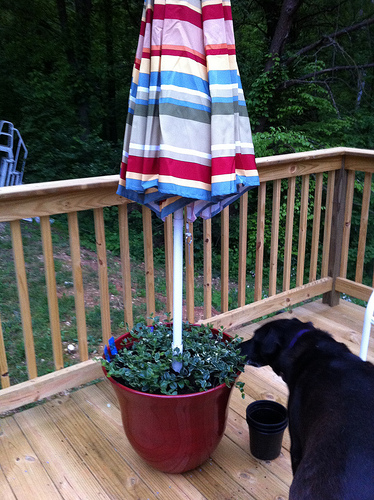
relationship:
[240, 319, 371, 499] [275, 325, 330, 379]
dog has collar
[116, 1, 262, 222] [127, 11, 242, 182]
umbrella has stripes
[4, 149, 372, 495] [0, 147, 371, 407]
deck has rails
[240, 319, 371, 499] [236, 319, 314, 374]
dog has head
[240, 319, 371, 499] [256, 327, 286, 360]
dog has ear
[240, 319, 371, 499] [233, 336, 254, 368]
dog has nose